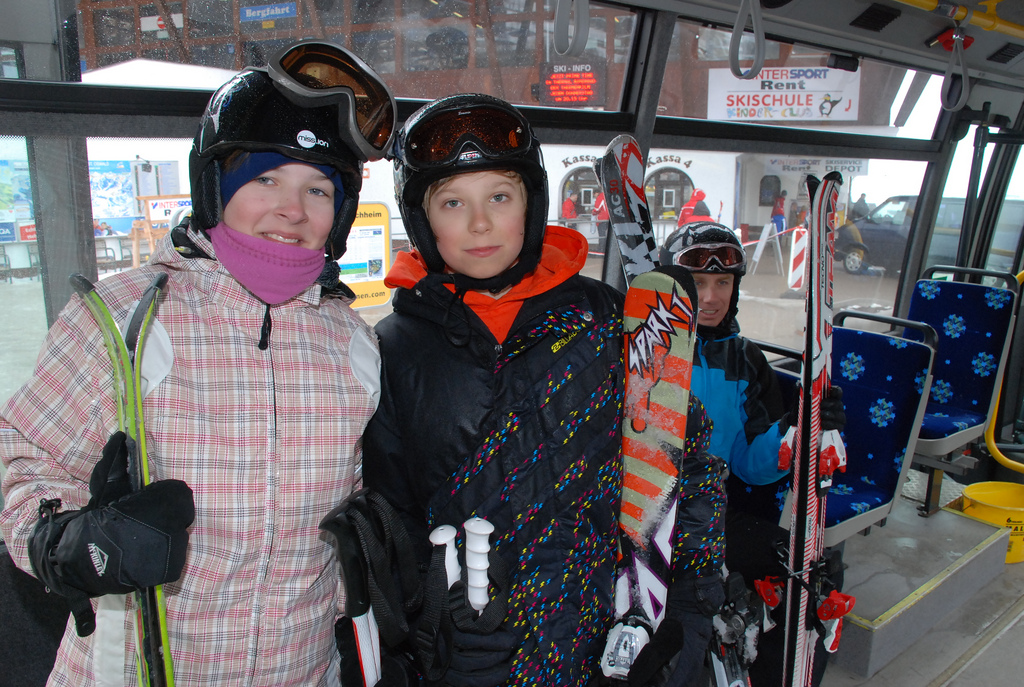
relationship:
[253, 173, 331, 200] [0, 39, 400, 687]
eye of a person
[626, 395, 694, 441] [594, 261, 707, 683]
stripe on ski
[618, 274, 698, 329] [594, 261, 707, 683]
stripe on ski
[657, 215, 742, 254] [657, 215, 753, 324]
light reflection on helmet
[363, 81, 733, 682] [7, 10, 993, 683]
person on bus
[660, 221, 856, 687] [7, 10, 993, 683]
person on bus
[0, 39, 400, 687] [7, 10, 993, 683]
person on bus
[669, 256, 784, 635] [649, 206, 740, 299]
person wearing helmet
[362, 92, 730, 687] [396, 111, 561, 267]
person wearing helmet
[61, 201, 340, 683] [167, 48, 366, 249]
person wearing helmet